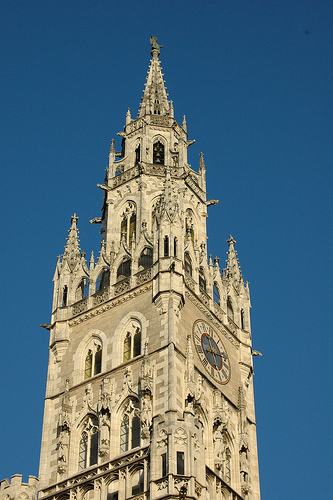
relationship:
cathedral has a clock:
[2, 34, 263, 500] [192, 318, 230, 385]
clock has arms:
[192, 318, 230, 385] [205, 337, 224, 371]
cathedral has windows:
[2, 34, 263, 500] [78, 325, 142, 476]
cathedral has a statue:
[2, 34, 263, 500] [149, 35, 163, 51]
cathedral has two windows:
[2, 34, 263, 500] [118, 209, 136, 246]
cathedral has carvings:
[2, 34, 263, 500] [58, 425, 151, 472]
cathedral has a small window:
[2, 34, 263, 500] [154, 139, 164, 167]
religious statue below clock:
[212, 423, 226, 470] [192, 318, 230, 385]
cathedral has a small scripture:
[2, 34, 263, 500] [156, 478, 168, 490]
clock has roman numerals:
[192, 318, 230, 385] [192, 320, 230, 382]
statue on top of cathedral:
[149, 35, 163, 51] [2, 34, 263, 500]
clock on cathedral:
[192, 318, 230, 385] [2, 34, 263, 500]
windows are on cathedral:
[78, 325, 142, 476] [2, 34, 263, 500]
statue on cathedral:
[149, 35, 163, 51] [2, 34, 263, 500]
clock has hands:
[192, 318, 230, 385] [205, 337, 224, 371]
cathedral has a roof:
[2, 34, 263, 500] [137, 59, 173, 119]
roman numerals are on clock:
[192, 320, 230, 382] [192, 318, 230, 385]